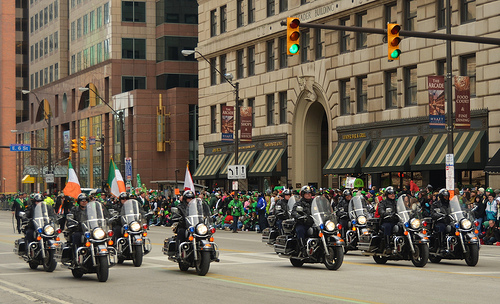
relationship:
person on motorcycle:
[68, 189, 95, 257] [273, 195, 345, 270]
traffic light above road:
[285, 15, 303, 52] [0, 206, 499, 304]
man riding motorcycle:
[292, 184, 312, 261] [273, 195, 345, 270]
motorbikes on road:
[15, 178, 482, 274] [2, 270, 496, 302]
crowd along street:
[1, 185, 498, 241] [0, 206, 500, 302]